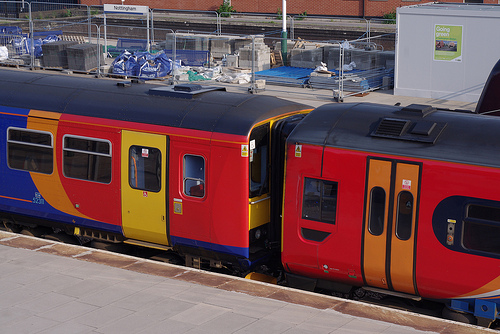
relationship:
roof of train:
[218, 90, 269, 134] [19, 87, 483, 294]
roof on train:
[218, 90, 269, 134] [19, 87, 483, 294]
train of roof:
[19, 87, 483, 294] [218, 90, 269, 134]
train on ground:
[19, 87, 483, 294] [37, 244, 237, 333]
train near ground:
[19, 87, 483, 294] [37, 244, 237, 333]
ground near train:
[37, 244, 237, 333] [19, 87, 483, 294]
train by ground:
[19, 87, 483, 294] [37, 244, 237, 333]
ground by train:
[37, 244, 237, 333] [19, 87, 483, 294]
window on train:
[126, 142, 164, 201] [19, 87, 483, 294]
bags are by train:
[99, 25, 190, 81] [19, 87, 483, 294]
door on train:
[357, 156, 435, 302] [19, 87, 483, 294]